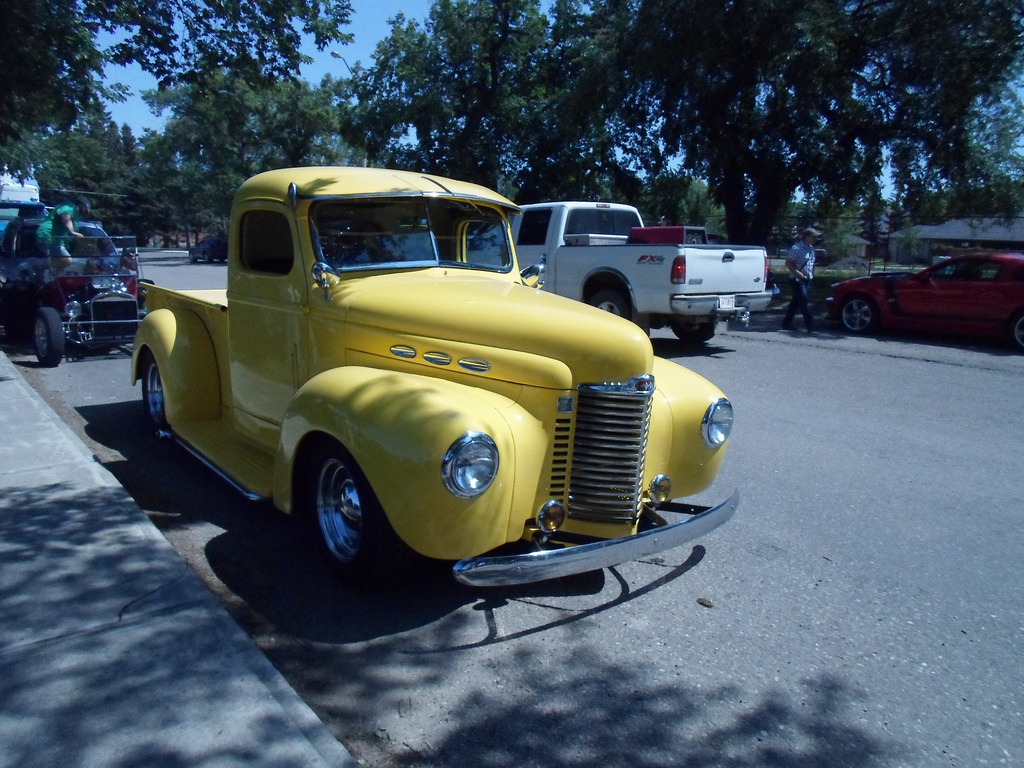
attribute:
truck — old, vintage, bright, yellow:
[125, 161, 758, 619]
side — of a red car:
[829, 251, 983, 332]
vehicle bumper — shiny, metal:
[448, 487, 745, 598]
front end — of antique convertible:
[31, 243, 153, 364]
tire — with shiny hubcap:
[291, 431, 404, 600]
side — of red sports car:
[822, 245, 993, 332]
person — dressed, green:
[20, 157, 94, 326]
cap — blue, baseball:
[795, 196, 845, 251]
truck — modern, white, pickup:
[106, 146, 852, 715]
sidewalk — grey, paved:
[26, 401, 264, 764]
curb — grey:
[145, 505, 314, 763]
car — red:
[864, 233, 1020, 350]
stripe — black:
[871, 286, 1010, 334]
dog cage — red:
[624, 200, 724, 255]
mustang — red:
[804, 203, 1018, 467]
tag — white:
[717, 304, 750, 317]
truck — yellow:
[363, 397, 538, 458]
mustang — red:
[828, 235, 1017, 324]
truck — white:
[599, 185, 801, 345]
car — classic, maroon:
[10, 201, 168, 348]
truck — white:
[504, 182, 786, 349]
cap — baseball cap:
[796, 221, 823, 239]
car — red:
[833, 249, 1021, 332]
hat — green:
[57, 201, 77, 212]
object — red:
[632, 223, 712, 260]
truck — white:
[476, 188, 779, 314]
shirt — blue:
[783, 245, 827, 276]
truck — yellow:
[94, 137, 767, 632]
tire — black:
[303, 463, 405, 604]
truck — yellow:
[103, 150, 736, 650]